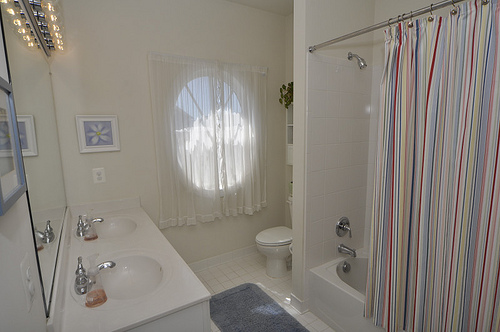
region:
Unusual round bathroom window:
[122, 46, 291, 228]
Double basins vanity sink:
[65, 199, 180, 317]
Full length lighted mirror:
[2, 1, 74, 313]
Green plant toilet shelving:
[275, 62, 296, 126]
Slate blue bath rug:
[207, 284, 318, 327]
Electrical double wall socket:
[11, 247, 44, 314]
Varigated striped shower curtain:
[371, 16, 483, 326]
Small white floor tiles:
[191, 245, 265, 279]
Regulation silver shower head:
[340, 44, 374, 79]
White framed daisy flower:
[69, 111, 133, 155]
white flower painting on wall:
[70, 101, 126, 161]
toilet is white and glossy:
[248, 214, 299, 285]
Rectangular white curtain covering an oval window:
[141, 37, 279, 226]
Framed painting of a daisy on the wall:
[65, 107, 123, 150]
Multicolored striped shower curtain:
[370, 12, 498, 319]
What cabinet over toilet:
[271, 68, 307, 235]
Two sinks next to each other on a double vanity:
[45, 173, 197, 330]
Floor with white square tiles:
[216, 262, 256, 279]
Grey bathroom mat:
[200, 273, 332, 328]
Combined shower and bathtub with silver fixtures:
[307, 20, 387, 321]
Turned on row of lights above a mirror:
[2, 0, 82, 57]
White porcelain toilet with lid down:
[252, 173, 309, 286]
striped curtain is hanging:
[363, 0, 499, 330]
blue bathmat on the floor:
[209, 280, 311, 330]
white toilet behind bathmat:
[255, 192, 295, 278]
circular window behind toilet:
[171, 75, 258, 190]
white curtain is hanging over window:
[145, 51, 267, 228]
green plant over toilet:
[278, 80, 295, 107]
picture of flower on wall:
[75, 112, 121, 154]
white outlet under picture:
[91, 165, 106, 183]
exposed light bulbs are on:
[30, 0, 66, 52]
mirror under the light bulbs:
[0, 0, 67, 317]